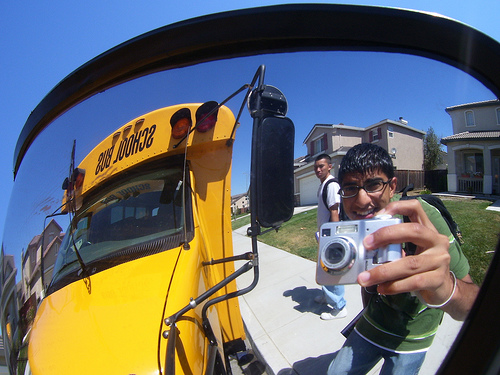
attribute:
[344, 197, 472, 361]
shirt — green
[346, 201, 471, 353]
gree shirt — green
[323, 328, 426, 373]
blue jeans — light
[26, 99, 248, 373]
bus — school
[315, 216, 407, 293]
camera — silver, small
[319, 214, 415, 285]
camera — silver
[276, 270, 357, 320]
sneakers — white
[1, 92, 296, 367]
bus — yellow